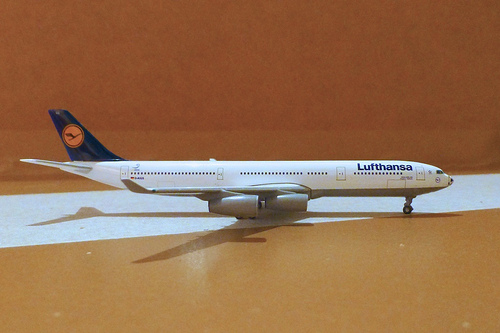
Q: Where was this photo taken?
A: An airport.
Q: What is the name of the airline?
A: Lufthansa.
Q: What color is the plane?
A: White.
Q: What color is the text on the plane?
A: Blue.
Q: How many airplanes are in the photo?
A: One.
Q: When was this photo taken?
A: Daytime.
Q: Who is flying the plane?
A: A pilot.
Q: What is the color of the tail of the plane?
A: Blue.